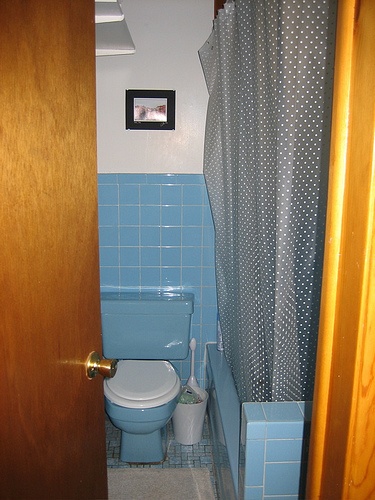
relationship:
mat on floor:
[107, 468, 206, 500] [164, 444, 213, 499]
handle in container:
[186, 334, 198, 389] [182, 378, 202, 391]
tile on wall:
[99, 172, 196, 290] [123, 0, 213, 293]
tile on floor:
[167, 442, 213, 467] [164, 444, 213, 499]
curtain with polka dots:
[200, 0, 331, 397] [276, 157, 294, 194]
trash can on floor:
[172, 384, 207, 445] [164, 444, 213, 499]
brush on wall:
[190, 336, 198, 389] [123, 0, 213, 293]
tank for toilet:
[101, 294, 195, 357] [96, 290, 194, 464]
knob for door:
[85, 350, 118, 380] [0, 0, 108, 497]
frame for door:
[307, 0, 372, 499] [0, 0, 108, 497]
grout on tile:
[156, 181, 165, 293] [99, 172, 196, 290]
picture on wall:
[125, 88, 175, 130] [123, 0, 213, 293]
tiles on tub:
[263, 402, 304, 498] [207, 343, 305, 499]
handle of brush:
[185, 340, 199, 388] [190, 336, 198, 389]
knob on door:
[85, 350, 118, 380] [0, 0, 108, 497]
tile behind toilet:
[99, 172, 196, 290] [96, 290, 194, 464]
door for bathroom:
[0, 0, 108, 497] [92, 0, 301, 497]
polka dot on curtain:
[298, 113, 306, 119] [200, 0, 331, 397]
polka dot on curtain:
[305, 79, 311, 87] [200, 0, 331, 397]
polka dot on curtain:
[309, 39, 315, 47] [200, 0, 331, 397]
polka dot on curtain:
[309, 181, 319, 190] [200, 0, 331, 397]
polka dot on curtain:
[276, 270, 280, 277] [200, 0, 331, 397]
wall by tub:
[123, 0, 213, 293] [207, 343, 305, 499]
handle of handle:
[185, 340, 199, 388] [186, 334, 198, 389]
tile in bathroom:
[167, 442, 213, 467] [92, 0, 301, 497]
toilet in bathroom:
[96, 290, 194, 464] [92, 0, 301, 497]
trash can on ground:
[172, 384, 207, 445] [164, 444, 213, 499]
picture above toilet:
[125, 88, 175, 130] [96, 290, 194, 464]